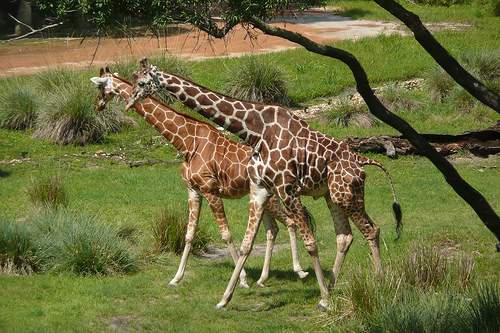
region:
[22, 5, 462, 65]
river by the grass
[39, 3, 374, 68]
river is very muddy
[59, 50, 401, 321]
two giraffes walking together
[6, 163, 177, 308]
green bushes in the grass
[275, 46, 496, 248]
tree limbs in the picture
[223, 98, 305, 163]
giraffes have a pattern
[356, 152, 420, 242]
giraffe has a tail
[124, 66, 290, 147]
giraffe has a long neck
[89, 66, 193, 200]
giraffe has a long neck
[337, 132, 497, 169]
rotted tree trunk in grass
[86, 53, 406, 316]
two giraffes on the plain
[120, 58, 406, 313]
the giraffe has dark brown spots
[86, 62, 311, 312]
the giraffe has light brown spots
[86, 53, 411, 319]
the giraffes are walking together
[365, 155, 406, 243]
the tail of the giraffe has a black hairy tip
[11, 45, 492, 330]
the savannah has green grass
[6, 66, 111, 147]
tufts of feather grass dot the area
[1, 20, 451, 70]
a mud hole is in the background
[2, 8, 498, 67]
a brown watering hole is behind the giraffes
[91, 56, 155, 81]
the giraffes have little horns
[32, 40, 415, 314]
Two giraffes walking together.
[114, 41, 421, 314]
One giraffe is a darker brown.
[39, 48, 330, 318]
One giraffe is a lighter brown with white ears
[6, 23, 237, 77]
They are near a river.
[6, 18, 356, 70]
The river is muddy and red.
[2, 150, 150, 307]
Large clumps of wild grass.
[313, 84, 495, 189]
A fallen log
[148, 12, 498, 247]
Small trees are leaning across landscape.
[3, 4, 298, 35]
Trees are standing on the other side of the river.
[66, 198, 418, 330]
There are bare, sandy patches amongst the grass.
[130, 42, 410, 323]
brown and tan giraffe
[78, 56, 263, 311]
brown and tan giraffe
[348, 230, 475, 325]
brown and green grass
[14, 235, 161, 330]
brown and green grass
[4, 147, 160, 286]
brown and green grass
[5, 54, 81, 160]
brown and green grass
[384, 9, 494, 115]
brown tree branch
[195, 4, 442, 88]
brown and green grass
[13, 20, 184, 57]
brown dirt on plain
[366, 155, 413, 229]
black and brown tail of giraffe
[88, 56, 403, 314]
The animal shown is giraffes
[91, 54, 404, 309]
Two giraffes are walking left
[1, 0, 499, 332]
The grass is green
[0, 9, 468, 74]
The water is brown and muddy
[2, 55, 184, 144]
Patch of monkey grass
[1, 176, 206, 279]
patch of monkey grass left of giraffe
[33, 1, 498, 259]
Tree branches cross in front of shot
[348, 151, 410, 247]
Giraffe tail has black hair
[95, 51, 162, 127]
Giraffe have horns on top of head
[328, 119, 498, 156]
Wood log laying on ground